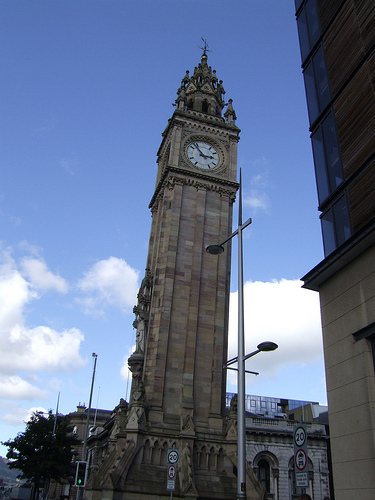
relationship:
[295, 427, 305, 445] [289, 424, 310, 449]
20 on sign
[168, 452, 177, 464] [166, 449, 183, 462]
20 on sign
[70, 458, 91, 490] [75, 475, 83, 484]
traffic light with green light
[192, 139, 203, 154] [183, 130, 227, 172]
hand of clock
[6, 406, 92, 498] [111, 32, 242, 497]
tree next to clock tower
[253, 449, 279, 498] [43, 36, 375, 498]
window on building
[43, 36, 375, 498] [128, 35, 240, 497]
building next to clock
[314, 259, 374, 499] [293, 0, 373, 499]
wall on side of building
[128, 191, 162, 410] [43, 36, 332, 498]
wall on side of building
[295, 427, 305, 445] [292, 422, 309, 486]
20 on sign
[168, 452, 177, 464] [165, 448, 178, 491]
20 on sign